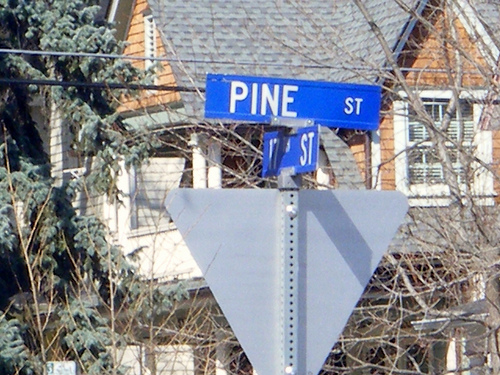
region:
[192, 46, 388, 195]
the signs are blue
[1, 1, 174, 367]
the leaves of tree are green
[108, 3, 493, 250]
the building is orange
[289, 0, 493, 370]
the tree has no leaves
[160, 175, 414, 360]
the back of sign is gray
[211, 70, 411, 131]
the name of street is pine st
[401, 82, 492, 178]
the window has mini blinds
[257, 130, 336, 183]
the 2nd street name is 17th st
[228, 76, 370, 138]
the lettering is white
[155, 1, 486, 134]
the roof is gray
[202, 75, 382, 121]
blue street sign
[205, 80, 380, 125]
blue street sign with white text print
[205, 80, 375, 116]
blue street sign reading Pine St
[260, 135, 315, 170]
blue street sign reading 17th st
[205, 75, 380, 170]
two blue street signs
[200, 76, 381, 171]
two blue street signs with a white text print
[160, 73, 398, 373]
three signs on a metal pole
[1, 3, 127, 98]
lots of leaves on tree branches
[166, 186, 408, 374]
back of a triangular sign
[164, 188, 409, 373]
triangular sign on a motel pole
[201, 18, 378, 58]
Roof is grey color.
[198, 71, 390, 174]
Street board is blue color.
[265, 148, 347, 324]
Board is attached to the pole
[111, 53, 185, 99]
Wall is red color.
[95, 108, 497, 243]
Windows are white color.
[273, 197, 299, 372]
Pole is grey color.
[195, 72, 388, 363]
Three boards are attached to the pole.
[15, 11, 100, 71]
Leaves are green color.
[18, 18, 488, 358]
Day time picture.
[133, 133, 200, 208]
Reflection is seen in mirror.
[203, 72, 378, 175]
a pair of blue street signs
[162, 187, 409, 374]
the back of a metal street sign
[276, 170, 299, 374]
a metal pole that the signs are attached to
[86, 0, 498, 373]
a house behind the sign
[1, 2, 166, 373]
a large tree to the left of the sign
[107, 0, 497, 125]
the roof of the house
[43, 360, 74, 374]
a small white and green street sign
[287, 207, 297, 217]
a screw on the pole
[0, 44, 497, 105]
a pair of black power lines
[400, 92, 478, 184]
a window on the house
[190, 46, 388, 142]
blue sign with white writing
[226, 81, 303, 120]
the word pine in white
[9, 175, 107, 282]
trees next to building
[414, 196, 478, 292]
dead trees next to building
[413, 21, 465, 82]
brown house in background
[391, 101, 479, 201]
white window of house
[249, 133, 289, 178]
the number 17 on sign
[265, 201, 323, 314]
silver pole with holes in it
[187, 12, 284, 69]
gray roof of building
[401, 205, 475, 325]
gray tree near house